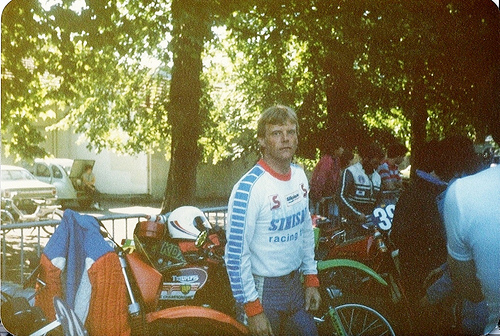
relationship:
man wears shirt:
[222, 105, 322, 335] [227, 161, 321, 316]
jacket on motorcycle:
[38, 211, 128, 335] [5, 208, 224, 336]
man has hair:
[222, 105, 322, 335] [256, 105, 299, 136]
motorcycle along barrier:
[5, 208, 224, 336] [1, 199, 345, 307]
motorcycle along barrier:
[136, 211, 231, 262] [1, 199, 345, 307]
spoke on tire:
[348, 310, 354, 336] [322, 301, 398, 335]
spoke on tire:
[361, 312, 368, 334] [322, 301, 398, 335]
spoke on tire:
[366, 323, 385, 335] [322, 301, 398, 335]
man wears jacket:
[341, 144, 382, 230] [340, 165, 382, 234]